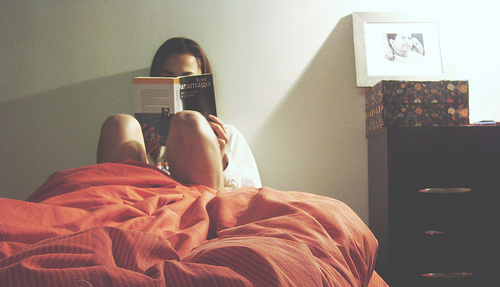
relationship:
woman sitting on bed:
[98, 38, 263, 187] [0, 160, 389, 285]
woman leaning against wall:
[98, 38, 263, 187] [0, 1, 499, 224]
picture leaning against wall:
[353, 9, 458, 87] [0, 1, 499, 224]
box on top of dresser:
[366, 81, 469, 129] [366, 124, 498, 284]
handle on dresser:
[418, 187, 471, 194] [366, 124, 498, 284]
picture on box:
[353, 9, 458, 87] [366, 81, 469, 129]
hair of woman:
[151, 36, 211, 75] [98, 38, 263, 187]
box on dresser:
[366, 81, 469, 129] [366, 124, 498, 284]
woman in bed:
[98, 38, 263, 187] [0, 160, 389, 285]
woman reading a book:
[98, 38, 263, 187] [134, 74, 217, 143]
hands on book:
[141, 116, 230, 163] [134, 74, 217, 143]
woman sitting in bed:
[98, 38, 263, 187] [0, 160, 389, 285]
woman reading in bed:
[98, 38, 263, 187] [0, 160, 389, 285]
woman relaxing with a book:
[98, 38, 263, 187] [134, 74, 217, 143]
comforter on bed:
[0, 162, 380, 286] [0, 160, 389, 285]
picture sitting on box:
[353, 9, 458, 87] [366, 81, 469, 129]